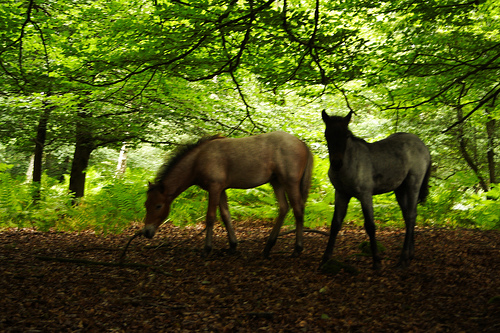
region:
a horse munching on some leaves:
[133, 130, 311, 256]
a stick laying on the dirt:
[31, 226, 155, 278]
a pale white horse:
[320, 108, 437, 269]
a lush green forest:
[0, 1, 498, 106]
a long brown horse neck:
[138, 140, 197, 239]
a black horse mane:
[148, 133, 212, 183]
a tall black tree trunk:
[63, 40, 99, 222]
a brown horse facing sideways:
[141, 123, 313, 267]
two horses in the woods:
[132, 104, 433, 269]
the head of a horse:
[126, 163, 197, 247]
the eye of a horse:
[151, 196, 170, 216]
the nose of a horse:
[134, 214, 171, 244]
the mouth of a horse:
[140, 220, 173, 257]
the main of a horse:
[145, 117, 232, 192]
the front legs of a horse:
[182, 168, 259, 277]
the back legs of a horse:
[262, 178, 311, 259]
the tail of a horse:
[285, 153, 316, 210]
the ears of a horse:
[303, 105, 384, 127]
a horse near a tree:
[121, 55, 330, 243]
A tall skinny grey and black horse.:
[316, 110, 431, 274]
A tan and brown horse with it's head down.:
[142, 130, 315, 257]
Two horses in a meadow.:
[143, 108, 433, 271]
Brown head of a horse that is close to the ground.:
[141, 179, 171, 239]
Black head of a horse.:
[320, 106, 355, 173]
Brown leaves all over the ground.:
[1, 224, 499, 329]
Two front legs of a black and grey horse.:
[318, 188, 383, 273]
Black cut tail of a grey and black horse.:
[419, 158, 430, 204]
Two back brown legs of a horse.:
[257, 175, 306, 260]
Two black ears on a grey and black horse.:
[321, 108, 353, 120]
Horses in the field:
[131, 116, 430, 258]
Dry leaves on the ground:
[153, 264, 258, 311]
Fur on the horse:
[141, 142, 195, 176]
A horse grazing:
[108, 122, 300, 242]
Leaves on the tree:
[122, 23, 235, 93]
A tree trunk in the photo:
[69, 120, 91, 195]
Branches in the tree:
[80, 37, 170, 109]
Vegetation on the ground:
[33, 187, 133, 235]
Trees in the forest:
[15, 29, 139, 161]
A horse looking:
[310, 113, 429, 269]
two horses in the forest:
[102, 67, 470, 279]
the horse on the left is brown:
[131, 111, 325, 238]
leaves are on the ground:
[92, 211, 374, 320]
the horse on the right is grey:
[303, 91, 465, 293]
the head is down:
[116, 164, 198, 261]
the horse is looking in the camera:
[302, 88, 369, 213]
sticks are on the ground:
[27, 219, 312, 299]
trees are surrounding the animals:
[65, 8, 484, 223]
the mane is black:
[147, 127, 224, 197]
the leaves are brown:
[167, 234, 391, 325]